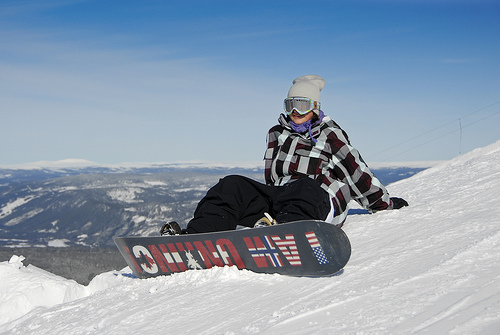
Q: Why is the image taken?
A: Rememberance.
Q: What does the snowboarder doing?
A: Sitting in snow.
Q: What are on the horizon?
A: Several mountain.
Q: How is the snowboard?
A: Black.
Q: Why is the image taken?
A: Remembrance.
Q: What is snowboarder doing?
A: Reclining on snowy slope.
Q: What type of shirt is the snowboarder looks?
A: Checks.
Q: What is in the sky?
A: Thin, white clouds.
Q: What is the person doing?
A: Sitting on snow bank.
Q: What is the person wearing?
A: Plaid shirt.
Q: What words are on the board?
A: I am.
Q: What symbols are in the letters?
A: Flags.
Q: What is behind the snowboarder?
A: Blue sky.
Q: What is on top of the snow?
A: Snowboarder.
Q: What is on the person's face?
A: Goggles.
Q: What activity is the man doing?
A: Snowboard.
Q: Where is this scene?
A: Ski slope.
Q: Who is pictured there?
A: A guy.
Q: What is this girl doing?
A: Sitting.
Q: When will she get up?
A: After she rests.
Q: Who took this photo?
A: Her friend.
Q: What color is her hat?
A: White.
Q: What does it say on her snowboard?
A: I am unhinc.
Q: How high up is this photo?
A: Top of a mountain.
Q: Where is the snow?
A: Everywhere.